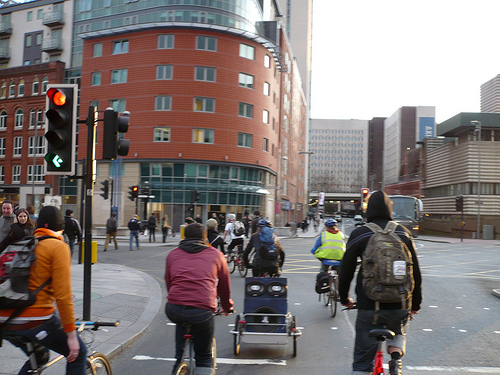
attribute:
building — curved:
[15, 12, 335, 259]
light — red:
[42, 76, 86, 172]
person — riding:
[1, 204, 88, 374]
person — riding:
[315, 217, 342, 317]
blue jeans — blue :
[162, 301, 222, 370]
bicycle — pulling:
[231, 254, 306, 365]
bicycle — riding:
[358, 311, 400, 373]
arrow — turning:
[46, 151, 71, 176]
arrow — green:
[47, 155, 66, 170]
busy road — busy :
[164, 200, 487, 332]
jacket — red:
[158, 239, 236, 311]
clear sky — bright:
[320, 5, 483, 117]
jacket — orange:
[8, 236, 125, 316]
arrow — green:
[43, 150, 73, 169]